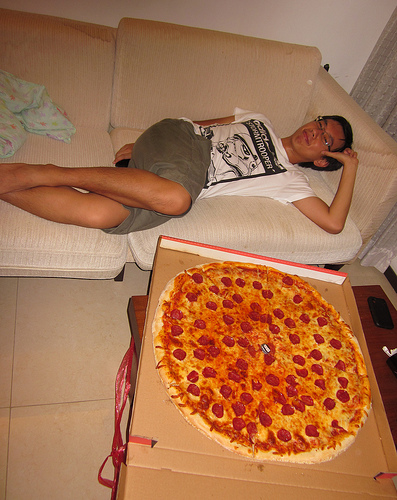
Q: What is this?
A: Pizza.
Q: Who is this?
A: Person.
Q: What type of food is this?
A: Pizza.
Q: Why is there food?
A: For eating.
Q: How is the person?
A: Lain.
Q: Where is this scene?
A: In a living room.